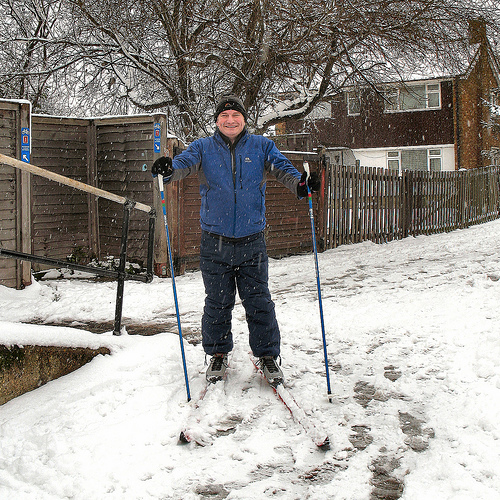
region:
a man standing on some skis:
[111, 97, 363, 455]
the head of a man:
[210, 93, 245, 140]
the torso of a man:
[185, 133, 267, 240]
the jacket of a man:
[142, 142, 333, 223]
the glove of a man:
[152, 158, 175, 177]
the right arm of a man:
[161, 133, 201, 182]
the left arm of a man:
[252, 139, 304, 201]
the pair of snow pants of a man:
[192, 220, 294, 374]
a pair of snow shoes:
[195, 338, 290, 387]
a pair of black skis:
[190, 360, 330, 468]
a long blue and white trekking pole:
[154, 178, 194, 401]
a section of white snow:
[0, 325, 195, 497]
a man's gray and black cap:
[212, 95, 251, 117]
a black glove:
[147, 155, 174, 177]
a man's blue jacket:
[170, 130, 307, 238]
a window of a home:
[424, 81, 444, 114]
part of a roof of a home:
[350, 36, 476, 83]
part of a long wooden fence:
[327, 161, 498, 249]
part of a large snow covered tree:
[22, 0, 480, 142]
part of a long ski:
[275, 383, 328, 453]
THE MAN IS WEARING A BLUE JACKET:
[163, 123, 298, 253]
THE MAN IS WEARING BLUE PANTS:
[182, 220, 309, 385]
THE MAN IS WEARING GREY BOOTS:
[192, 345, 298, 401]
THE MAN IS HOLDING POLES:
[140, 140, 350, 441]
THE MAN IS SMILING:
[215, 120, 256, 138]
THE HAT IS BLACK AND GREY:
[207, 97, 257, 124]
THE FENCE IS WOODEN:
[308, 142, 496, 244]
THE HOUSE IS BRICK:
[222, 20, 497, 220]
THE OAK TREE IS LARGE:
[2, 2, 493, 164]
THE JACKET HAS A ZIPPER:
[213, 139, 253, 245]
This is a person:
[129, 85, 381, 479]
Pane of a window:
[425, 90, 442, 108]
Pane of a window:
[423, 79, 442, 93]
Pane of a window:
[426, 147, 442, 158]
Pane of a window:
[428, 156, 440, 176]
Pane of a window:
[398, 147, 428, 178]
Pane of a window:
[386, 150, 400, 161]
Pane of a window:
[385, 158, 397, 184]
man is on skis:
[107, 0, 355, 443]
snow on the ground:
[42, 380, 114, 462]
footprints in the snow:
[310, 390, 429, 472]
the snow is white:
[181, 418, 311, 469]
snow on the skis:
[163, 385, 365, 457]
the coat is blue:
[213, 155, 267, 227]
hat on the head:
[197, 90, 247, 120]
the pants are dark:
[187, 274, 273, 361]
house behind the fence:
[321, 70, 481, 178]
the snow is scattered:
[342, 228, 497, 289]